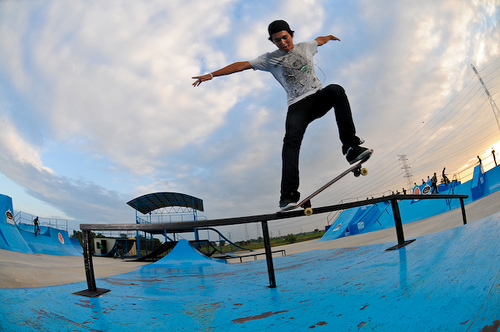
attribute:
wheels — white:
[303, 205, 311, 216]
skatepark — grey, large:
[2, 192, 498, 324]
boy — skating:
[189, 20, 367, 201]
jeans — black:
[280, 85, 362, 202]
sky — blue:
[11, 9, 186, 185]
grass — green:
[273, 236, 316, 241]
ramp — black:
[80, 222, 437, 282]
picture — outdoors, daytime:
[4, 1, 484, 332]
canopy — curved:
[127, 191, 203, 216]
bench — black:
[216, 246, 286, 266]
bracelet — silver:
[207, 72, 214, 78]